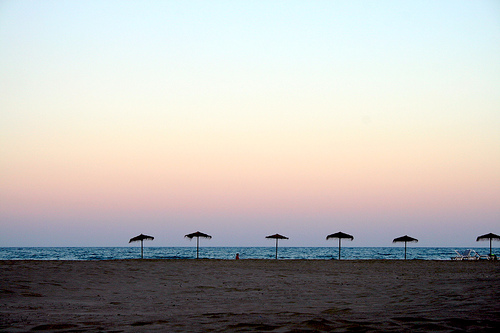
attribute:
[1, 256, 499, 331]
sand — brown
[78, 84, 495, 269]
sunset — pink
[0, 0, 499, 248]
sunset — colorful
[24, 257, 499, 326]
beach — sandy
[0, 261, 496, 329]
beach — sandy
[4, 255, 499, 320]
beach — sandy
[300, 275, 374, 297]
beach — sandy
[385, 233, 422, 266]
umbrellas — six